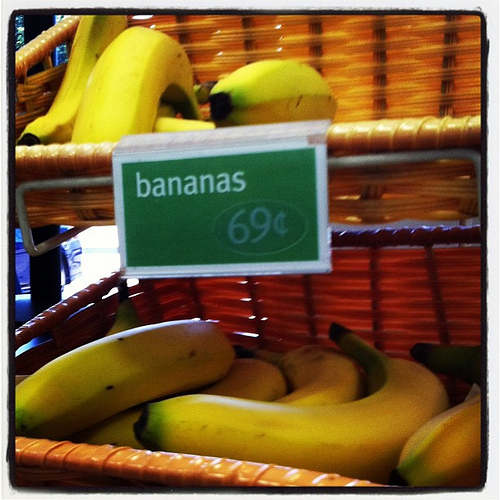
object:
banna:
[132, 319, 445, 487]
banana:
[69, 24, 200, 146]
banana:
[14, 316, 236, 444]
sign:
[110, 142, 334, 280]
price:
[225, 200, 292, 248]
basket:
[336, 19, 483, 216]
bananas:
[228, 339, 368, 411]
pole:
[359, 152, 416, 167]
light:
[79, 226, 120, 280]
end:
[130, 402, 166, 445]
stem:
[326, 319, 388, 367]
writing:
[134, 168, 246, 200]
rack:
[14, 146, 484, 259]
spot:
[105, 383, 117, 392]